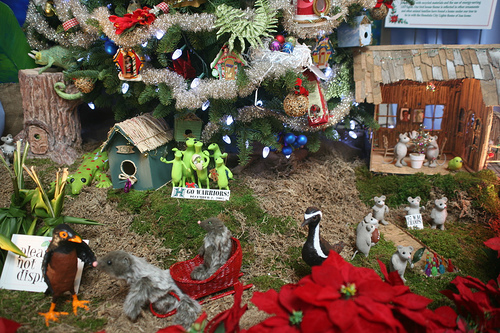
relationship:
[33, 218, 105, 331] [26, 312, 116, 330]
figurine sitting on turf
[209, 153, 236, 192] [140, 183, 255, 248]
figurine sitting on turf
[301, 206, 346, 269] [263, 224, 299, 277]
bird sitting on turf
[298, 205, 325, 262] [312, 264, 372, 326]
bird behind poinsettia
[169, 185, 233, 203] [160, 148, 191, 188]
sign below figurine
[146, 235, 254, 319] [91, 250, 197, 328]
sled pulled by animal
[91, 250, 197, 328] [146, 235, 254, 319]
animal pulling sled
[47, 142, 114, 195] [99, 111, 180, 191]
lizard by bird house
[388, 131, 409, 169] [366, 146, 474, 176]
mice on a porch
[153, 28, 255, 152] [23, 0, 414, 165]
lights on a christmas tree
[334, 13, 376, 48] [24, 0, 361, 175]
birdhouse on a tree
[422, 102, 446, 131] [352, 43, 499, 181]
window on a house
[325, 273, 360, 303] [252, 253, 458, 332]
center of a poinsettia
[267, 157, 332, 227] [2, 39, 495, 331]
straw on ground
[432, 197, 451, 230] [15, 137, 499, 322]
figurine on turf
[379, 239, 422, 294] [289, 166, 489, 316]
figurine on turf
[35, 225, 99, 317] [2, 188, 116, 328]
figurine on turf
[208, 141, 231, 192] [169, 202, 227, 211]
figurine on turf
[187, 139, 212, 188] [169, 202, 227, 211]
figurine on turf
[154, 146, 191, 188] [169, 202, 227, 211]
figurine on turf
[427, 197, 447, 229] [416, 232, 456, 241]
figurine on turf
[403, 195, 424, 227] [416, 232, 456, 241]
figurine on turf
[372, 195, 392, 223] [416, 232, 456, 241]
figurine on turf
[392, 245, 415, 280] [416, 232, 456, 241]
figurine on turf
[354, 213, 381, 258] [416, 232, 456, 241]
figurine on turf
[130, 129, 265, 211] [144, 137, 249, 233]
figurine on turf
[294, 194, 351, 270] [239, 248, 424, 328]
skunk crawling under poisettia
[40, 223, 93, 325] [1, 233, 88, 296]
crow standing next card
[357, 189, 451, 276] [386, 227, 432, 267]
mice standing around path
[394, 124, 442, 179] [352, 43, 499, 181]
mice in house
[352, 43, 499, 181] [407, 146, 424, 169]
house with pot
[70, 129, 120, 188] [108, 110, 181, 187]
lizard next to bird house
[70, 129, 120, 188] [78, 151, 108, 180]
lizard with spots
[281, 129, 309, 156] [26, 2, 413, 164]
blue balls hanging from christmas tree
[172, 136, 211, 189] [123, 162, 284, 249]
figurine on top grass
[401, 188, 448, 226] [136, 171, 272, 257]
teletubbies on top grass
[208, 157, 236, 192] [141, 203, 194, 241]
figurine on top grass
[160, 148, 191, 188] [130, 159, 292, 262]
figurine on top grass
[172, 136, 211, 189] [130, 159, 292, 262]
figurine on top grass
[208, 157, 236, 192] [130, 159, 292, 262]
figurine on top grass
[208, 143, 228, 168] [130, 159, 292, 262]
figurine on top grass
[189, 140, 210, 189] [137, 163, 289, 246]
figurine on top grass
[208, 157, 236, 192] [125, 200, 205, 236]
figurine on top grass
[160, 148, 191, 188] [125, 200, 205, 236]
figurine on top grass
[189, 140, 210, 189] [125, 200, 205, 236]
figurine on top grass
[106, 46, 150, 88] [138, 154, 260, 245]
teletubbies on top grass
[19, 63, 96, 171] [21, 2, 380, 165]
log under christmas tree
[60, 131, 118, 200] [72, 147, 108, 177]
figure with spots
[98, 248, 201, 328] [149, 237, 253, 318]
stuffed animal pulling sled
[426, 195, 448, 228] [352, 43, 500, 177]
mouse in house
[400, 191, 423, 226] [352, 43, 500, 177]
mouse in house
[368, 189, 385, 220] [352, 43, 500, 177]
mouse in house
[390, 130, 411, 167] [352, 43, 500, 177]
mouse in house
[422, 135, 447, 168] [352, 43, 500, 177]
mice in house